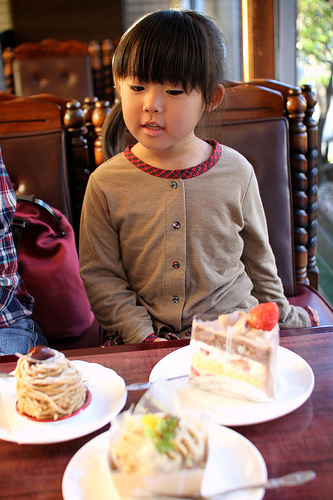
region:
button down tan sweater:
[76, 135, 318, 343]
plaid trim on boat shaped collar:
[121, 136, 223, 180]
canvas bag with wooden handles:
[9, 193, 105, 348]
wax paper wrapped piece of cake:
[183, 299, 281, 406]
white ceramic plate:
[60, 416, 268, 498]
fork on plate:
[148, 468, 319, 498]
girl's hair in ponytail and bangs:
[100, 6, 227, 159]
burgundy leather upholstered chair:
[62, 75, 332, 329]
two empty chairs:
[1, 36, 103, 234]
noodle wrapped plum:
[9, 343, 92, 421]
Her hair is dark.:
[113, 4, 242, 89]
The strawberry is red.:
[237, 296, 278, 333]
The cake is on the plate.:
[171, 307, 277, 405]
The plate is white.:
[149, 316, 306, 426]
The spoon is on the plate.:
[169, 451, 315, 499]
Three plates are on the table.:
[4, 333, 317, 498]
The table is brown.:
[16, 346, 329, 493]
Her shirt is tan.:
[78, 149, 290, 335]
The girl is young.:
[67, 1, 330, 346]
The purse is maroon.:
[10, 187, 103, 345]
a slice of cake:
[177, 290, 289, 416]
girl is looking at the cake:
[100, 64, 213, 172]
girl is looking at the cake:
[106, 57, 301, 408]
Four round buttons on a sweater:
[159, 176, 185, 311]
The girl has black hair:
[109, 6, 226, 154]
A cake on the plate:
[145, 299, 317, 430]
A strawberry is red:
[244, 295, 284, 337]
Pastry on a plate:
[1, 339, 130, 448]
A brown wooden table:
[2, 323, 331, 498]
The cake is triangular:
[179, 297, 282, 406]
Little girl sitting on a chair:
[71, 8, 318, 347]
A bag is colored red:
[8, 189, 98, 345]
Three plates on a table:
[0, 302, 330, 498]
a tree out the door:
[298, 3, 331, 89]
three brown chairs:
[14, 45, 318, 207]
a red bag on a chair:
[16, 198, 94, 328]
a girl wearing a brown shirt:
[100, 12, 288, 325]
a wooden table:
[262, 411, 329, 470]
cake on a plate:
[150, 320, 326, 417]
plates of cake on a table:
[4, 325, 309, 497]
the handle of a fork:
[211, 464, 319, 498]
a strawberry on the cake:
[249, 302, 282, 325]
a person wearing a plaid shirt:
[0, 170, 43, 326]